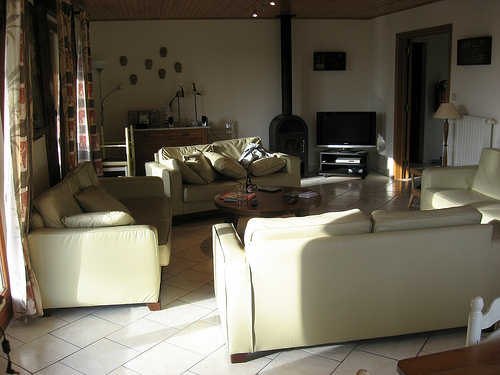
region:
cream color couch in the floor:
[221, 220, 448, 336]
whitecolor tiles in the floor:
[94, 323, 199, 373]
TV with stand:
[314, 107, 381, 178]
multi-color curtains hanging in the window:
[59, 16, 96, 156]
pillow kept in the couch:
[193, 145, 280, 182]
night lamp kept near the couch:
[429, 100, 463, 174]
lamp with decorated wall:
[92, 36, 226, 110]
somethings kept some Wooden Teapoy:
[216, 170, 322, 214]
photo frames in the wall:
[303, 38, 356, 78]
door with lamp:
[395, 26, 464, 201]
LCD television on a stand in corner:
[310, 105, 380, 182]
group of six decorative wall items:
[112, 36, 190, 96]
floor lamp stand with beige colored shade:
[430, 93, 469, 183]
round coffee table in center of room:
[205, 178, 324, 250]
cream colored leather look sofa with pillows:
[24, 152, 178, 317]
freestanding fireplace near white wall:
[264, 15, 312, 175]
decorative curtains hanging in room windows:
[4, 2, 101, 334]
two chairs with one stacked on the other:
[90, 123, 137, 180]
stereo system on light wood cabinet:
[122, 105, 162, 132]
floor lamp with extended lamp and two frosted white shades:
[87, 52, 129, 165]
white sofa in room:
[217, 215, 497, 360]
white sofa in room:
[34, 165, 166, 316]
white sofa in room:
[146, 137, 301, 222]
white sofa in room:
[409, 148, 497, 213]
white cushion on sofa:
[64, 214, 131, 224]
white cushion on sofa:
[77, 182, 123, 216]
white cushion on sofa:
[172, 152, 199, 179]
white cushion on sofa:
[189, 152, 208, 174]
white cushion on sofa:
[212, 153, 248, 177]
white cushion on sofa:
[252, 157, 280, 172]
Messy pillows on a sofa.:
[154, 142, 284, 179]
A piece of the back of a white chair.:
[463, 286, 499, 343]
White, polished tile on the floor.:
[48, 321, 178, 368]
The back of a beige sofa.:
[197, 207, 499, 362]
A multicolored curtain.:
[3, 78, 32, 317]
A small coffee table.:
[222, 177, 322, 215]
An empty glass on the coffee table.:
[233, 181, 246, 206]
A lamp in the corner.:
[431, 103, 463, 165]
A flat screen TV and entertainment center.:
[310, 108, 378, 180]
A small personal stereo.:
[127, 110, 162, 128]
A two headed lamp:
[91, 58, 126, 125]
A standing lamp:
[432, 98, 459, 166]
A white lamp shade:
[433, 100, 467, 122]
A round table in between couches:
[213, 178, 323, 215]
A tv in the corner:
[310, 108, 383, 149]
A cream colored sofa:
[30, 165, 178, 312]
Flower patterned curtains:
[3, 30, 45, 322]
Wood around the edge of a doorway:
[390, 22, 456, 182]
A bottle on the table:
[241, 171, 259, 193]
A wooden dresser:
[126, 125, 212, 170]